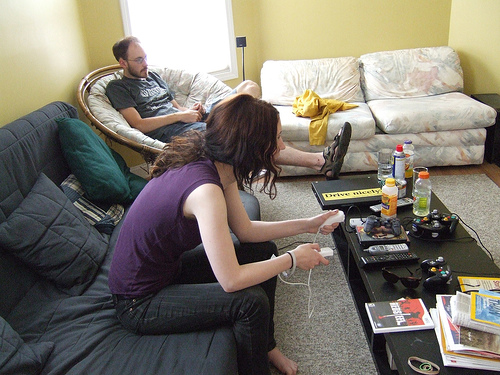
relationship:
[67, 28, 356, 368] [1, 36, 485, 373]
couple lounging in living room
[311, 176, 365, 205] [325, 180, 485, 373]
case sits on coffee table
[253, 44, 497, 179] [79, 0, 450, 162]
love seat against wall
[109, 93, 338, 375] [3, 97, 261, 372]
girl sitting on couch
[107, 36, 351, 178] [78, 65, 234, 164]
man sitting in chair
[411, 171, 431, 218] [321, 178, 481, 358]
bottle on table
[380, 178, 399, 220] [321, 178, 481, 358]
bottle on table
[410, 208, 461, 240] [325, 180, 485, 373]
game controllers on coffee table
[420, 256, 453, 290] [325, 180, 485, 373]
controller on coffee table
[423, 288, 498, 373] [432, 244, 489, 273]
magazine stack on coffee table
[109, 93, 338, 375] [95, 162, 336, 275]
girl wearing purple shirt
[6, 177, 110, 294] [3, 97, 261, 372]
throw pillow on couch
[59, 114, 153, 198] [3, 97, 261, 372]
throw pillow on couch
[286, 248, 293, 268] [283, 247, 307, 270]
black band on wrist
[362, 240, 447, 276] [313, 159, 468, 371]
remote control on table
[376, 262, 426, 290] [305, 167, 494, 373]
sun glasses on table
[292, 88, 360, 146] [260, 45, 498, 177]
clothing on sofa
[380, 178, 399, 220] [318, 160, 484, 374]
bottle on table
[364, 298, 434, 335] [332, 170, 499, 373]
box on coffee table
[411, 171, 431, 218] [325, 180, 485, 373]
bottle sits on coffee table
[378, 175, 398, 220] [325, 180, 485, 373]
bottle sits on coffee table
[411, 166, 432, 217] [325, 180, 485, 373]
bottle sits on coffee table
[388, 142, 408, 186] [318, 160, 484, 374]
wd-40 sitting on table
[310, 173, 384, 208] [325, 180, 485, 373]
laptop sitting on coffee table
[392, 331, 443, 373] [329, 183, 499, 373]
bands sitting on coffee table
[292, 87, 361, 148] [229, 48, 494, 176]
blanket sits on sofa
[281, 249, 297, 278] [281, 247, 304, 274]
bracelet worn on wrist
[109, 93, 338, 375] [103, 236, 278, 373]
girl wearing jeans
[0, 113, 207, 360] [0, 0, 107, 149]
couch against wall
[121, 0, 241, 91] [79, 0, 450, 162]
window on wall